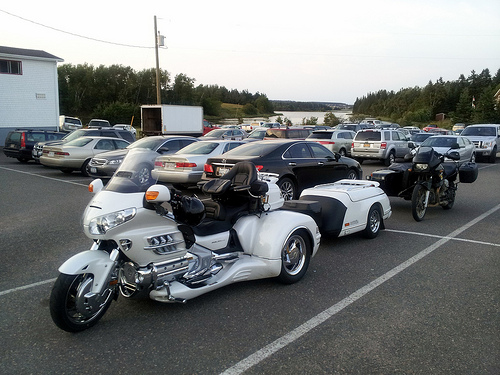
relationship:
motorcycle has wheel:
[52, 176, 322, 292] [43, 259, 142, 337]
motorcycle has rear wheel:
[52, 176, 322, 292] [267, 230, 324, 286]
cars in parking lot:
[211, 107, 414, 187] [398, 230, 497, 359]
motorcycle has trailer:
[52, 176, 322, 292] [306, 180, 408, 239]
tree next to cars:
[77, 59, 123, 105] [211, 107, 414, 187]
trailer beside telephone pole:
[137, 105, 206, 133] [143, 47, 170, 61]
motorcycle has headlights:
[52, 176, 322, 292] [138, 182, 161, 201]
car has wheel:
[258, 136, 327, 185] [277, 180, 304, 199]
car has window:
[258, 136, 327, 185] [304, 137, 323, 156]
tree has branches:
[77, 59, 123, 105] [184, 71, 203, 84]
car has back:
[258, 136, 327, 185] [200, 155, 236, 177]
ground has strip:
[246, 294, 378, 366] [330, 282, 374, 306]